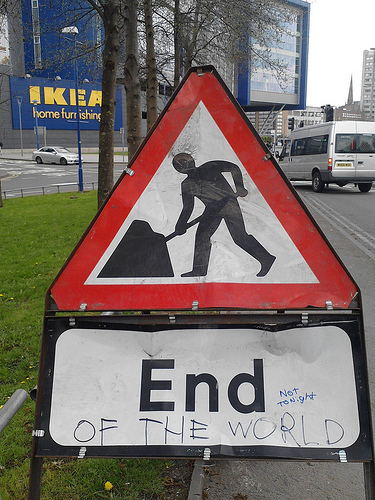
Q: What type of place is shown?
A: It is a street.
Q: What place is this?
A: It is a street.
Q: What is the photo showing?
A: It is showing a street.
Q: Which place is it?
A: It is a street.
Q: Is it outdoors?
A: Yes, it is outdoors.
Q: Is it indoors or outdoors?
A: It is outdoors.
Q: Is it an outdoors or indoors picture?
A: It is outdoors.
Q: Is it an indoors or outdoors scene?
A: It is outdoors.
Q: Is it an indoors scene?
A: No, it is outdoors.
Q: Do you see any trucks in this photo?
A: No, there are no trucks.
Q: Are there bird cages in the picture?
A: No, there are no bird cages.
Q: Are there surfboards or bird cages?
A: No, there are no bird cages or surfboards.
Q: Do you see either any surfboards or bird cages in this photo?
A: No, there are no bird cages or surfboards.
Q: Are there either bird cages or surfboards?
A: No, there are no bird cages or surfboards.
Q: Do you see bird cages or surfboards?
A: No, there are no bird cages or surfboards.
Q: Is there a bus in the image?
A: No, there are no buses.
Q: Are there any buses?
A: No, there are no buses.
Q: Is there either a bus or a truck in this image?
A: No, there are no buses or trucks.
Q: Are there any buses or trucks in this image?
A: No, there are no buses or trucks.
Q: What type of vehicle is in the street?
A: The vehicle is a car.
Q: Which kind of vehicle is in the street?
A: The vehicle is a car.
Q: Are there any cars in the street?
A: Yes, there is a car in the street.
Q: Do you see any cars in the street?
A: Yes, there is a car in the street.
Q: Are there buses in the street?
A: No, there is a car in the street.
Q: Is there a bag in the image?
A: No, there are no bags.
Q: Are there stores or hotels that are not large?
A: No, there is a store but it is large.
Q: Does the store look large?
A: Yes, the store is large.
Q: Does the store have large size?
A: Yes, the store is large.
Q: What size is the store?
A: The store is large.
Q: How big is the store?
A: The store is large.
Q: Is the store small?
A: No, the store is large.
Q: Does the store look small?
A: No, the store is large.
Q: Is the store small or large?
A: The store is large.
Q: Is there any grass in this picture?
A: Yes, there is grass.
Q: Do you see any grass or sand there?
A: Yes, there is grass.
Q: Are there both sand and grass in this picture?
A: No, there is grass but no sand.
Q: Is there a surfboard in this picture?
A: No, there are no surfboards.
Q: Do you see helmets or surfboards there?
A: No, there are no surfboards or helmets.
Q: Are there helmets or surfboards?
A: No, there are no surfboards or helmets.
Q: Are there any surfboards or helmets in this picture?
A: No, there are no surfboards or helmets.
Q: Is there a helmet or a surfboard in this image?
A: No, there are no surfboards or helmets.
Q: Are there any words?
A: Yes, there are words.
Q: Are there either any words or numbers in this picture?
A: Yes, there are words.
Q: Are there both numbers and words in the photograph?
A: No, there are words but no numbers.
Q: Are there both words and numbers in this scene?
A: No, there are words but no numbers.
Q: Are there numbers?
A: No, there are no numbers.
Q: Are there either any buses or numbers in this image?
A: No, there are no numbers or buses.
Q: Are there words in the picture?
A: Yes, there are words.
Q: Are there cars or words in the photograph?
A: Yes, there are words.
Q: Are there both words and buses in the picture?
A: No, there are words but no buses.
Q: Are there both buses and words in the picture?
A: No, there are words but no buses.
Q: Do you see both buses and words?
A: No, there are words but no buses.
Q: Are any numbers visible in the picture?
A: No, there are no numbers.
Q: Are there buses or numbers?
A: No, there are no numbers or buses.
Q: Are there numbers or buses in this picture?
A: No, there are no numbers or buses.